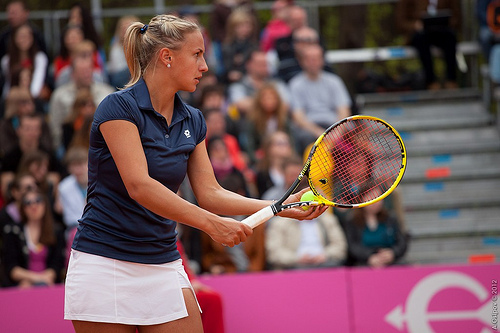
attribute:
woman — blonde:
[55, 8, 346, 332]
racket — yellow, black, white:
[209, 108, 409, 253]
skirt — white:
[59, 242, 213, 328]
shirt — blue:
[68, 86, 201, 269]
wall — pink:
[0, 270, 498, 332]